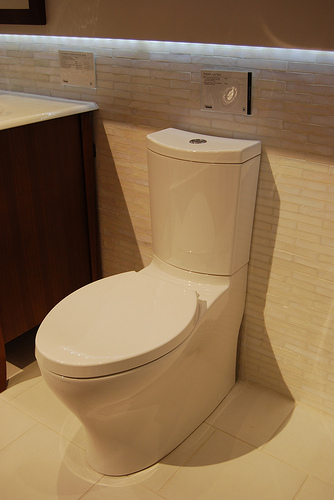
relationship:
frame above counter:
[0, 2, 54, 29] [1, 83, 81, 146]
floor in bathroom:
[2, 374, 332, 498] [2, 3, 332, 496]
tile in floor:
[74, 469, 166, 498] [0, 339, 333, 497]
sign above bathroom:
[195, 67, 254, 117] [0, 1, 333, 499]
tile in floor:
[235, 404, 330, 496] [10, 335, 323, 486]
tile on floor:
[218, 382, 333, 473] [0, 358, 332, 496]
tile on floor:
[152, 427, 303, 498] [0, 358, 332, 496]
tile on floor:
[291, 474, 333, 499] [0, 358, 332, 496]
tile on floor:
[9, 423, 85, 471] [0, 358, 332, 496]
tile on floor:
[0, 399, 37, 449] [0, 358, 332, 496]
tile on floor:
[152, 427, 303, 498] [0, 339, 333, 497]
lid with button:
[145, 126, 263, 165] [189, 135, 206, 145]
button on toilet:
[188, 137, 208, 145] [31, 124, 262, 474]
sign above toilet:
[203, 72, 247, 115] [31, 124, 262, 474]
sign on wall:
[203, 72, 247, 115] [246, 75, 313, 322]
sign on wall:
[56, 49, 96, 87] [3, 1, 329, 413]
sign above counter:
[56, 49, 96, 87] [4, 73, 110, 140]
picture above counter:
[1, 1, 52, 31] [0, 85, 103, 130]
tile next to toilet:
[1, 393, 35, 449] [32, 126, 264, 401]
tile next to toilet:
[9, 377, 88, 471] [32, 126, 264, 401]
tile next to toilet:
[1, 360, 45, 403] [32, 126, 264, 401]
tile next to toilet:
[9, 423, 85, 471] [31, 124, 262, 474]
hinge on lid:
[191, 289, 200, 298] [33, 268, 200, 377]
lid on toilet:
[33, 268, 200, 377] [31, 124, 262, 474]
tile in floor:
[11, 377, 87, 451] [0, 358, 332, 496]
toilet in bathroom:
[31, 124, 262, 474] [2, 3, 332, 496]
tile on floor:
[9, 423, 85, 471] [0, 339, 333, 497]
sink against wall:
[1, 87, 103, 389] [3, 1, 329, 413]